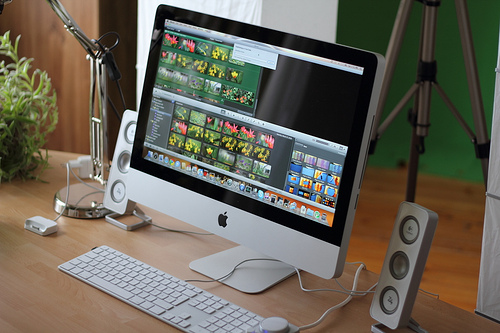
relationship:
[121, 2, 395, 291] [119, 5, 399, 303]
monitor on computer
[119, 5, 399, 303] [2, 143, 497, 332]
computer on desk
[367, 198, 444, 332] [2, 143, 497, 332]
speaker on desk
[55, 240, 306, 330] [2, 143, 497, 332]
keyboard on desk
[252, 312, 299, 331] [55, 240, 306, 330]
knob on keyboard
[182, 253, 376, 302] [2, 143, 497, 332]
wire on desk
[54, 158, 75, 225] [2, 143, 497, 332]
wire on desk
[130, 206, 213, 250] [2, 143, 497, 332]
wire on desk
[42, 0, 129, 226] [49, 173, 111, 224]
desk lamp has base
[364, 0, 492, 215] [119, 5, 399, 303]
tripod behind computer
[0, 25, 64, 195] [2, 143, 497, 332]
plant on desk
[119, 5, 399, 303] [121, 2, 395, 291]
computer has monitor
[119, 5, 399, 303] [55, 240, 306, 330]
computer has keyboard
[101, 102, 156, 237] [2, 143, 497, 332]
speaker on desk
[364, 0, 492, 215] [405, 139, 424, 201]
tripod has base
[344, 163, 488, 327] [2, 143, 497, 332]
floor under desk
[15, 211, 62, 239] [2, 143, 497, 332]
charger on desk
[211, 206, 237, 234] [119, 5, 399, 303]
logo on front of computer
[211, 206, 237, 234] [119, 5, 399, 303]
logo in front of computer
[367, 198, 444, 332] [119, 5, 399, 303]
speaker by computer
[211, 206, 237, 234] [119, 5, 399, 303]
logo on computer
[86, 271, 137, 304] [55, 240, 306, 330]
spacebar on keyboard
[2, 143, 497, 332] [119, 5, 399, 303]
desk beneath computer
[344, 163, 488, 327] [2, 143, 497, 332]
floor beneath desk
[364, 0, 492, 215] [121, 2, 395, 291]
tripod near monitor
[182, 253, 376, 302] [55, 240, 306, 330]
wire connected to keyboard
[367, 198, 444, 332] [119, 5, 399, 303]
speaker next to computer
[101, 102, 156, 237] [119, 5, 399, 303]
speaker next to computer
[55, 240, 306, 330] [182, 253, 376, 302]
keyboard has wire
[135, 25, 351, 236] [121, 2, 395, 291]
website page on monitor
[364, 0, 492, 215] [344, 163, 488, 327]
tripod on floor